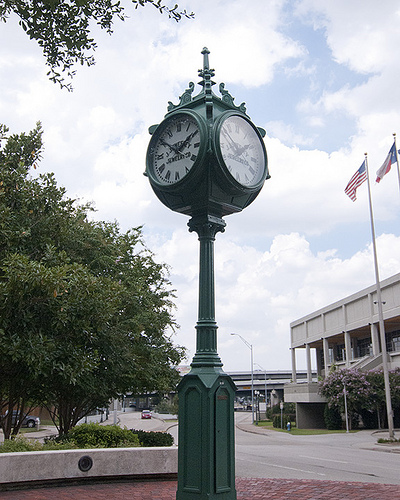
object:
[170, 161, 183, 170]
white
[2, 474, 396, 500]
bricks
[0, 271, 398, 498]
area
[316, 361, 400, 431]
tree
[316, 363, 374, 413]
leaves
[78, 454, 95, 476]
hole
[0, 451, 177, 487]
wall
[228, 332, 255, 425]
street light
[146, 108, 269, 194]
clock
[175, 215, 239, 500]
pole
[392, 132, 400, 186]
pole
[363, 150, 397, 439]
pole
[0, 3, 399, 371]
clouds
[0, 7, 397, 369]
sky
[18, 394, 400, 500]
road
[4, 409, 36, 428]
car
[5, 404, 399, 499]
ground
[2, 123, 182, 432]
trees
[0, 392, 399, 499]
street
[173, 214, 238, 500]
clock pillar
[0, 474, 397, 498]
floor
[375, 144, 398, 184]
flag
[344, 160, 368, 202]
flag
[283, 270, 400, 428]
building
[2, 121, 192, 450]
tree garden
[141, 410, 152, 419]
car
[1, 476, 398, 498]
sidewalk